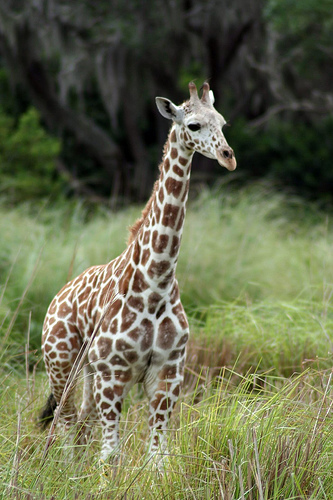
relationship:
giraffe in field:
[39, 81, 241, 478] [1, 367, 330, 497]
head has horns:
[159, 74, 245, 173] [184, 79, 216, 103]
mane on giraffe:
[121, 125, 174, 246] [39, 81, 241, 478]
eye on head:
[184, 120, 203, 141] [159, 74, 245, 173]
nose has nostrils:
[220, 146, 236, 159] [223, 152, 232, 160]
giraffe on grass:
[39, 81, 241, 478] [0, 304, 326, 498]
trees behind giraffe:
[0, 0, 332, 200] [39, 81, 241, 478]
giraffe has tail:
[39, 81, 241, 478] [36, 400, 61, 429]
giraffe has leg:
[39, 81, 241, 478] [93, 382, 123, 477]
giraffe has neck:
[39, 81, 241, 478] [115, 147, 192, 283]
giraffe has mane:
[39, 81, 241, 478] [121, 125, 174, 246]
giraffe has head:
[39, 81, 241, 478] [159, 74, 245, 173]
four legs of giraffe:
[44, 346, 183, 496] [39, 81, 241, 478]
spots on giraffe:
[49, 173, 188, 437] [39, 81, 241, 478]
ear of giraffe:
[155, 99, 176, 117] [39, 81, 241, 478]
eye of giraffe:
[184, 120, 203, 141] [39, 81, 241, 478]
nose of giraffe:
[222, 145, 237, 172] [39, 81, 241, 478]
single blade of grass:
[289, 472, 297, 495] [0, 304, 326, 498]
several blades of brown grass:
[214, 433, 265, 497] [210, 409, 328, 489]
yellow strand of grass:
[11, 406, 23, 485] [0, 304, 326, 498]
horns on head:
[184, 79, 216, 103] [159, 74, 245, 173]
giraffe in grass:
[39, 81, 241, 478] [0, 304, 326, 498]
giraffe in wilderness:
[39, 81, 241, 478] [1, 0, 329, 496]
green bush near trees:
[0, 105, 73, 218] [0, 0, 332, 200]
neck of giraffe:
[115, 147, 192, 283] [39, 81, 241, 478]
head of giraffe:
[159, 74, 245, 173] [39, 81, 241, 478]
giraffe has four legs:
[39, 81, 241, 478] [44, 346, 183, 496]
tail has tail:
[36, 400, 61, 429] [36, 380, 57, 431]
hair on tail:
[40, 401, 50, 427] [36, 400, 61, 429]